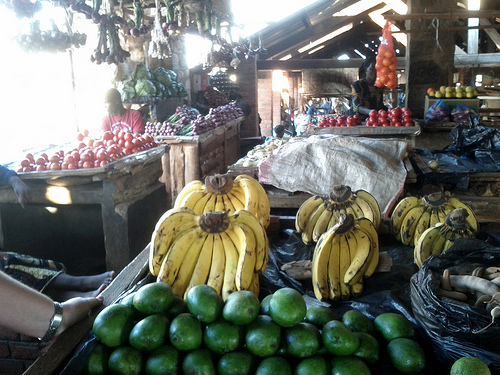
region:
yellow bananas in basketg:
[149, 165, 281, 308]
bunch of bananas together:
[130, 208, 271, 295]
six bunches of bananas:
[155, 175, 471, 284]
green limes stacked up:
[90, 289, 410, 374]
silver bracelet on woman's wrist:
[28, 300, 65, 346]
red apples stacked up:
[74, 123, 121, 159]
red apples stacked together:
[353, 105, 417, 130]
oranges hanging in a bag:
[368, 24, 405, 92]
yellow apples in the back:
[431, 81, 471, 96]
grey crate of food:
[0, 150, 159, 190]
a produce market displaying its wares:
[1, 2, 496, 372]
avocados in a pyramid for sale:
[82, 278, 439, 371]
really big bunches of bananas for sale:
[144, 168, 496, 308]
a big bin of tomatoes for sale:
[7, 118, 163, 179]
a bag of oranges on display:
[369, 12, 404, 99]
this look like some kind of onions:
[140, 96, 247, 142]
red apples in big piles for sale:
[311, 98, 421, 135]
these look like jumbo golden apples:
[424, 80, 485, 107]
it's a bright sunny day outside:
[1, 2, 326, 170]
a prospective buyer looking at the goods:
[1, 258, 110, 350]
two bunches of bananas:
[148, 171, 267, 286]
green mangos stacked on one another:
[93, 285, 418, 374]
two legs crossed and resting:
[27, 257, 112, 293]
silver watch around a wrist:
[45, 298, 66, 349]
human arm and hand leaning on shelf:
[0, 268, 100, 337]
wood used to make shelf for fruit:
[121, 268, 137, 277]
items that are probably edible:
[456, 263, 496, 308]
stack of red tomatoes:
[21, 124, 143, 174]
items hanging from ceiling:
[94, 19, 129, 63]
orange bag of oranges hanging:
[370, 15, 397, 91]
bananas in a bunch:
[155, 202, 257, 279]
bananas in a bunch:
[302, 214, 376, 291]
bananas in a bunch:
[420, 217, 467, 256]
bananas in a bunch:
[401, 194, 466, 226]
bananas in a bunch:
[307, 187, 388, 217]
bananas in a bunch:
[190, 177, 267, 210]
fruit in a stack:
[132, 284, 177, 304]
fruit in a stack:
[185, 283, 220, 315]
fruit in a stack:
[212, 287, 260, 317]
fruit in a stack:
[262, 282, 301, 319]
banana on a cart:
[130, 190, 168, 271]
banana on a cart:
[159, 237, 204, 287]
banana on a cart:
[197, 231, 234, 291]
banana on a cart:
[226, 216, 266, 299]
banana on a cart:
[242, 180, 276, 219]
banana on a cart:
[285, 193, 315, 239]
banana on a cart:
[303, 198, 328, 293]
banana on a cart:
[327, 225, 346, 288]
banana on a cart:
[345, 248, 375, 301]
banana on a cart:
[406, 217, 439, 273]